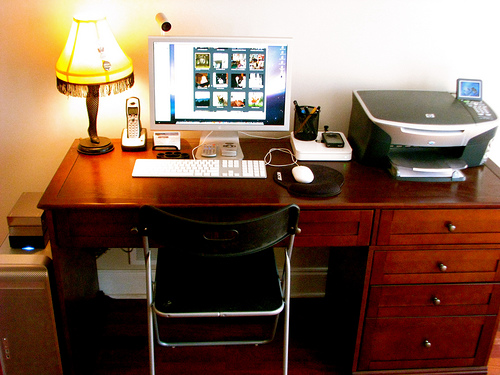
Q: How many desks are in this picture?
A: One.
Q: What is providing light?
A: A lamp.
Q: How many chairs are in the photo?
A: One.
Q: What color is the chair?
A: Black.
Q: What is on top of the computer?
A: A webcam.